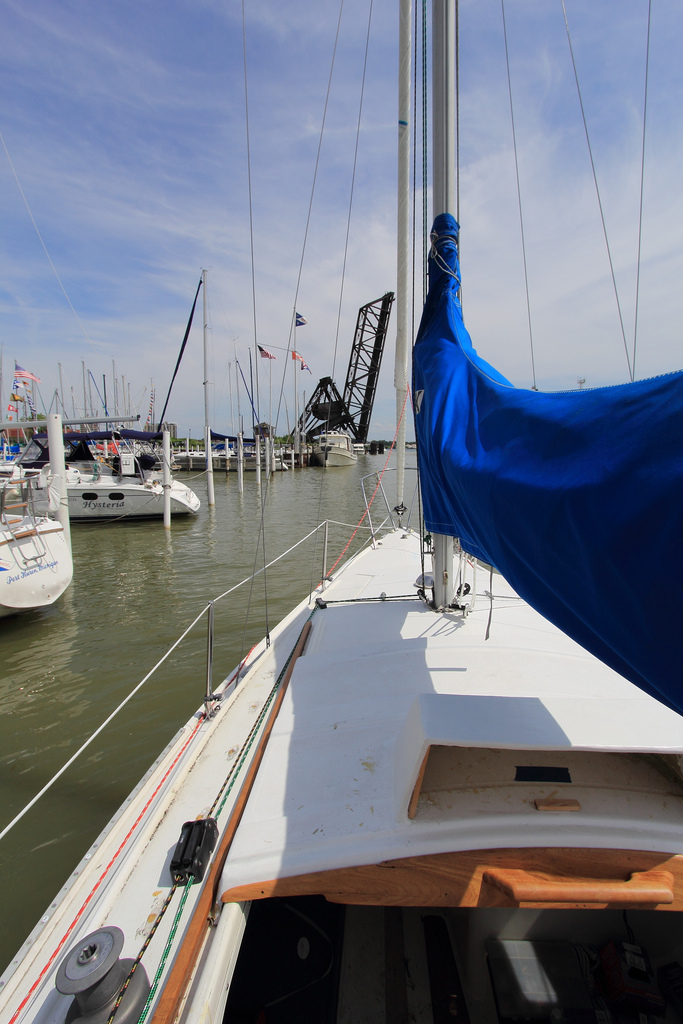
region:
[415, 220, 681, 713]
a blue sail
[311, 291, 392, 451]
a black drawbridge in the up possition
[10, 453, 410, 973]
water in the marina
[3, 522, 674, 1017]
deck of a white boat with blue sail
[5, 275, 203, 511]
a white boat called Hysteria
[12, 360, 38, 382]
an American flag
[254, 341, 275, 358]
an American flag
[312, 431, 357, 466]
a white boat docked near the bridge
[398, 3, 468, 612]
the mast of the sail boat with blue sail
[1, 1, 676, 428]
partly cloudy sky above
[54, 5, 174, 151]
white clouds in blue sky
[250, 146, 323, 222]
white clouds in blue sky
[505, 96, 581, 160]
white clouds in blue sky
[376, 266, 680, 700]
blue sail of boat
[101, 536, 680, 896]
white boat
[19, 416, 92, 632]
white boat in green water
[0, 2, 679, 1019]
a boat on the water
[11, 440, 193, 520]
a boat on the water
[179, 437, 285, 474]
a boat on the water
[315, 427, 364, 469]
a boat on the water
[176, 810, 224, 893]
the contraption is black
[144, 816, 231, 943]
rope going through contraption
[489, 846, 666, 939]
the handle is wooden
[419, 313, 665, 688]
the fabric is blue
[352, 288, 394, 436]
the bridge is lifted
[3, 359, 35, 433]
the flags are on the rope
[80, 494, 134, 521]
words are on the boat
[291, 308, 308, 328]
A flag flying on a rope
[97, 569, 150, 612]
still green water in the bay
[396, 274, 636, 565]
blue mast on the boat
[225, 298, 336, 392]
colorful flags on mast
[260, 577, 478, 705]
mast's shadow on the deck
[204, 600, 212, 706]
boat has a pole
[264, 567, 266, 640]
boat has a pole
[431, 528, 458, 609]
boat has a pole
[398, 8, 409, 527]
boat has a pole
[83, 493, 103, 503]
boat has a window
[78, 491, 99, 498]
boat has a window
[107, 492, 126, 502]
boat has a window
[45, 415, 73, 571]
pole is white and tall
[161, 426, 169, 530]
pole is white and tall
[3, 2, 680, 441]
thin white clouds in blue sky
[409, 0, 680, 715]
blue canvas hanging from pole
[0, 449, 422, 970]
reflection on water surface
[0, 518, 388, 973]
white rope hanging on metal poles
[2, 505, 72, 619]
stern on white boat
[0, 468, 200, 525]
side of docked boat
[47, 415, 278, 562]
row of white poles in water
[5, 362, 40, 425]
waving flags on rope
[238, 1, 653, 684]
vertical cables suspended in midair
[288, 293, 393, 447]
side of open drawbridge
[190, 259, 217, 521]
A pole coming out from the water.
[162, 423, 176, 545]
A pole coming out from the water.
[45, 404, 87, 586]
A pole coming out from the water.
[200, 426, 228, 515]
A pole coming out from the water.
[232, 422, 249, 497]
A pole coming out from the water.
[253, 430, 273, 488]
A pole coming out from the water.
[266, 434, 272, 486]
A pole coming out from the water.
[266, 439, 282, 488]
A pole coming out from the water.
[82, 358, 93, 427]
A pole coming out from the water.